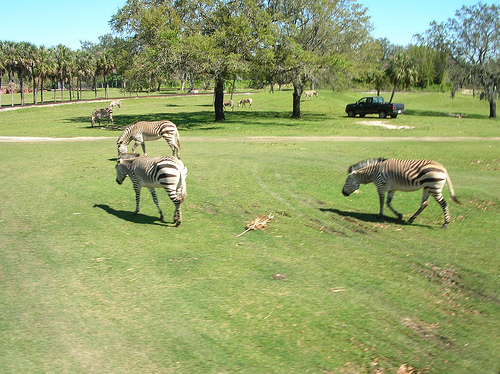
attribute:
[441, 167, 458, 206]
tail — long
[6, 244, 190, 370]
field — green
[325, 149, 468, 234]
zebra — black and white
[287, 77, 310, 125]
tree trunk — brown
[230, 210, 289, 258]
leaf — large, brown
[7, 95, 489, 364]
field — green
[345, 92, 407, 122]
pickup truck — dark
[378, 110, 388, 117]
wheel — large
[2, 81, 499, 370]
grass — green, pale green, short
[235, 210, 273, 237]
leaf — large, gold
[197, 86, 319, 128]
trunks — brown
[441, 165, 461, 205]
tail — black and white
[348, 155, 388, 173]
mane — long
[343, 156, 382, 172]
comb — large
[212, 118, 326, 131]
grass — lush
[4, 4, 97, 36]
sky — blue